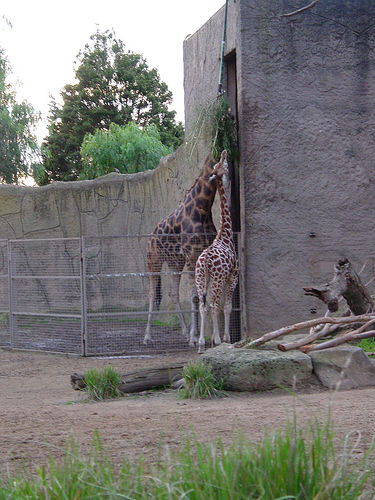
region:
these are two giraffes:
[141, 98, 242, 347]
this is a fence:
[63, 238, 162, 349]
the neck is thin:
[211, 178, 229, 231]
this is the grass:
[240, 440, 328, 499]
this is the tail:
[195, 259, 207, 306]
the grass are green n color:
[225, 428, 324, 494]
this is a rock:
[231, 343, 277, 392]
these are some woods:
[293, 307, 351, 351]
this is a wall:
[281, 76, 343, 206]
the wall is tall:
[264, 37, 351, 168]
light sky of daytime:
[0, 1, 222, 184]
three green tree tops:
[0, 22, 181, 182]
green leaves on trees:
[82, 122, 169, 175]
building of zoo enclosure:
[184, 1, 373, 342]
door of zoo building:
[185, 1, 243, 341]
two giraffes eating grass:
[141, 95, 237, 349]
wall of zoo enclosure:
[0, 153, 184, 313]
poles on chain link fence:
[2, 232, 240, 356]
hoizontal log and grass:
[70, 362, 178, 397]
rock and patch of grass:
[182, 342, 310, 399]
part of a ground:
[144, 403, 187, 458]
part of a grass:
[244, 446, 280, 496]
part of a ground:
[144, 390, 177, 442]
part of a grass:
[255, 435, 277, 474]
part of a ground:
[157, 402, 181, 436]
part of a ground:
[111, 393, 169, 453]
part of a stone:
[213, 355, 247, 409]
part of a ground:
[150, 425, 176, 460]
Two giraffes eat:
[139, 99, 253, 351]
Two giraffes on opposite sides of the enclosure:
[140, 98, 254, 354]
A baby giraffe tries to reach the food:
[193, 145, 253, 353]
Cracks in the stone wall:
[6, 167, 165, 232]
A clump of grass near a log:
[85, 366, 131, 398]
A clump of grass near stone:
[185, 340, 279, 400]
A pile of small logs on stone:
[251, 312, 372, 346]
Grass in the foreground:
[4, 439, 374, 496]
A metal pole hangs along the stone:
[217, 1, 235, 93]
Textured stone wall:
[246, 20, 371, 108]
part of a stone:
[235, 341, 280, 397]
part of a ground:
[142, 398, 155, 411]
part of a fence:
[141, 299, 158, 357]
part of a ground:
[172, 413, 200, 457]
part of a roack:
[250, 350, 293, 428]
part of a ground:
[211, 397, 250, 463]